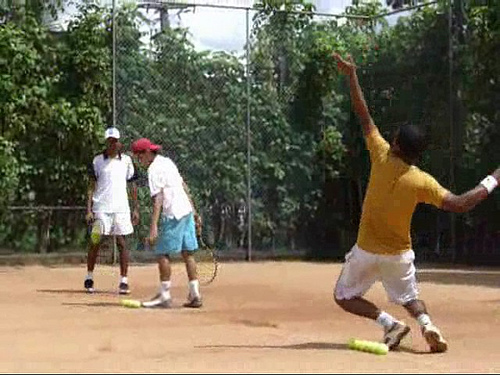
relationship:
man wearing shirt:
[328, 48, 499, 353] [356, 127, 447, 252]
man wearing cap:
[132, 136, 206, 310] [131, 136, 161, 155]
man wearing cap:
[82, 126, 141, 296] [103, 126, 122, 142]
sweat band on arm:
[481, 173, 498, 192] [421, 165, 499, 215]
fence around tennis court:
[0, 1, 499, 260] [2, 259, 499, 374]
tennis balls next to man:
[346, 335, 390, 357] [328, 48, 499, 353]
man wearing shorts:
[132, 136, 206, 310] [153, 212, 199, 257]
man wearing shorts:
[328, 48, 499, 353] [334, 243, 420, 305]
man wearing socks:
[328, 48, 499, 353] [373, 307, 433, 327]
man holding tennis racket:
[132, 136, 206, 310] [196, 222, 219, 287]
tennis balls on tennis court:
[346, 335, 390, 357] [2, 259, 499, 374]